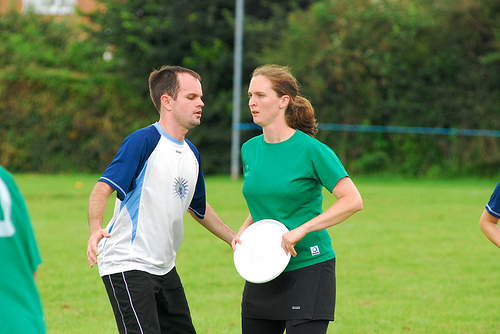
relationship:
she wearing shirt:
[229, 63, 368, 332] [239, 128, 349, 272]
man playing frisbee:
[75, 60, 234, 334] [228, 216, 293, 287]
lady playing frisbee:
[229, 62, 364, 332] [228, 216, 293, 287]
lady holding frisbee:
[229, 62, 364, 332] [228, 216, 293, 287]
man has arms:
[76, 52, 235, 332] [77, 127, 154, 266]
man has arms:
[76, 52, 235, 332] [178, 139, 233, 249]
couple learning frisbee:
[82, 60, 364, 331] [228, 216, 293, 287]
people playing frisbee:
[81, 55, 362, 330] [228, 216, 293, 287]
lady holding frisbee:
[229, 62, 364, 332] [231, 221, 296, 282]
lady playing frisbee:
[229, 62, 364, 332] [234, 218, 293, 283]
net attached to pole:
[235, 121, 495, 188] [231, 9, 242, 181]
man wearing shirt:
[75, 60, 234, 334] [93, 120, 205, 279]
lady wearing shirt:
[229, 62, 364, 332] [239, 128, 349, 272]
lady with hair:
[229, 62, 364, 332] [245, 62, 322, 137]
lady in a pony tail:
[229, 62, 364, 332] [286, 90, 321, 136]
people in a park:
[81, 55, 362, 330] [8, 11, 489, 326]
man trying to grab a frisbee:
[75, 60, 234, 334] [235, 214, 294, 284]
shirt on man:
[93, 120, 205, 279] [75, 60, 234, 334]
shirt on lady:
[239, 128, 349, 272] [229, 62, 364, 332]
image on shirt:
[166, 164, 205, 207] [88, 124, 219, 284]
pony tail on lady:
[285, 93, 319, 135] [229, 62, 364, 332]